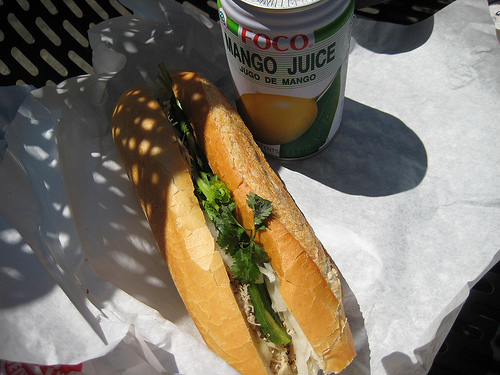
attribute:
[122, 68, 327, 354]
sandwhich — big, long, brown, thick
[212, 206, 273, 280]
lettuce — green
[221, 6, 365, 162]
can — green, white, mango, close, red, sitting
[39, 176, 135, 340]
paper — white, thick, used, holding, close